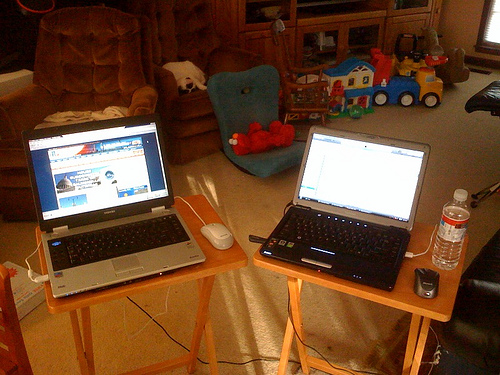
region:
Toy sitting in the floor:
[215, 106, 287, 167]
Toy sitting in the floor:
[271, 34, 329, 122]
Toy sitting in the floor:
[318, 61, 384, 130]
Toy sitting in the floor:
[382, 56, 448, 111]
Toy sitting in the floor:
[417, 28, 472, 89]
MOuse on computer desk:
[410, 249, 434, 309]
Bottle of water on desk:
[425, 177, 473, 306]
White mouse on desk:
[190, 214, 234, 264]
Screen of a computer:
[33, 104, 188, 231]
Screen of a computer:
[288, 102, 440, 249]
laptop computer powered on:
[16, 105, 212, 309]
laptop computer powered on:
[242, 113, 436, 296]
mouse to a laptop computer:
[407, 262, 449, 303]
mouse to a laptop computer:
[195, 218, 236, 255]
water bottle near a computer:
[422, 183, 479, 275]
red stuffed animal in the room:
[220, 113, 299, 167]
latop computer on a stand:
[11, 103, 275, 374]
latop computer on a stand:
[242, 111, 479, 373]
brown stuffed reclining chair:
[0, 9, 169, 221]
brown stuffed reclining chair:
[131, 0, 275, 175]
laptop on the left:
[26, 109, 207, 300]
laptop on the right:
[257, 120, 433, 300]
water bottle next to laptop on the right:
[431, 184, 470, 274]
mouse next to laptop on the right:
[411, 264, 439, 302]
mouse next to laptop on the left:
[198, 218, 235, 251]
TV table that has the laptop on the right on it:
[253, 182, 473, 374]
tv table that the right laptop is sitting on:
[251, 175, 473, 373]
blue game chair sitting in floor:
[197, 61, 324, 187]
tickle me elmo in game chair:
[229, 108, 295, 160]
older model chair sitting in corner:
[3, 5, 168, 225]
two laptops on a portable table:
[20, 88, 477, 373]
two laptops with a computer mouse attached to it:
[18, 105, 488, 368]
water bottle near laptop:
[241, 114, 497, 339]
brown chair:
[131, 2, 308, 170]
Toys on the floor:
[317, 48, 448, 126]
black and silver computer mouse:
[408, 259, 447, 308]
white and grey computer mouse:
[194, 219, 246, 256]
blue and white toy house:
[323, 63, 385, 123]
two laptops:
[21, 109, 430, 321]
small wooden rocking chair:
[257, 18, 358, 136]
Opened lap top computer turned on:
[258, 122, 429, 292]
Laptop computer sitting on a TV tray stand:
[20, 113, 207, 298]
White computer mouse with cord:
[176, 194, 235, 250]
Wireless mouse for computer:
[412, 267, 439, 299]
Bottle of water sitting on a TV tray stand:
[430, 186, 472, 271]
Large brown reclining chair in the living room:
[0, 4, 159, 223]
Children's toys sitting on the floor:
[321, 44, 449, 121]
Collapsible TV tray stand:
[34, 190, 251, 373]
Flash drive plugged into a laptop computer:
[247, 233, 267, 245]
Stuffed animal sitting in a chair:
[226, 118, 296, 158]